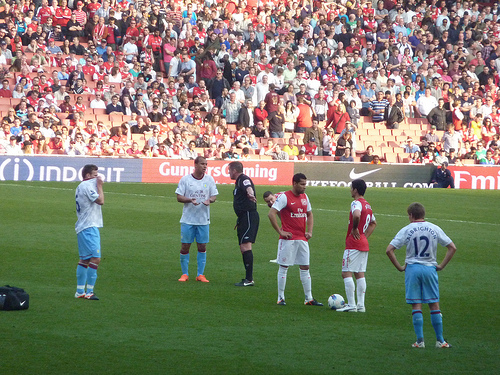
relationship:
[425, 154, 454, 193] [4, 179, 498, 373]
man sitting on grass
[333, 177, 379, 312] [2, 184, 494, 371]
player on field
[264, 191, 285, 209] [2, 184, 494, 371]
player on field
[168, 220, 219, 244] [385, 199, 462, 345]
shorts on player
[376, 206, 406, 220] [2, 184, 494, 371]
line on field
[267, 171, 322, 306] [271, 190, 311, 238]
player wearing jersey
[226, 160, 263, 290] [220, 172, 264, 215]
referee wearing shirt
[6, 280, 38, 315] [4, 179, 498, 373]
bag in grass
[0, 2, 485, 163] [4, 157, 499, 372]
spectators watching game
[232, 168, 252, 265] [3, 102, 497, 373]
official on field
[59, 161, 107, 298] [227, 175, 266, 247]
player wearing jersey